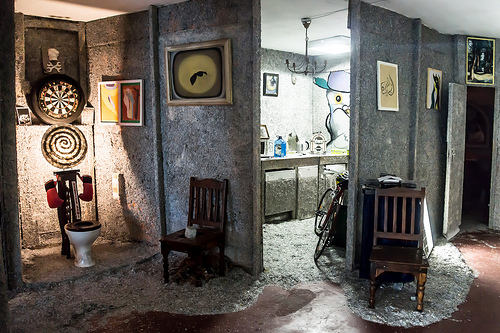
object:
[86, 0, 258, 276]
wall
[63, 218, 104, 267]
toilet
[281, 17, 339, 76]
chandelier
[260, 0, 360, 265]
kitchen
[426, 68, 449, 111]
picture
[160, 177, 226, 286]
chair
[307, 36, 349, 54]
light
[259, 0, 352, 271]
door way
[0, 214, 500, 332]
floor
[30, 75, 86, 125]
dartboard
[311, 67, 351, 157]
drawing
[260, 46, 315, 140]
wall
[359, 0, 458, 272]
wall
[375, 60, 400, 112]
drawing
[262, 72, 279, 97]
drawing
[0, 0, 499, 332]
picture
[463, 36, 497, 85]
picture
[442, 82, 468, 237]
door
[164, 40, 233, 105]
picture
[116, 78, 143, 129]
picture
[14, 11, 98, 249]
wall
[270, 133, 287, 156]
bottle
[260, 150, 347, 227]
table